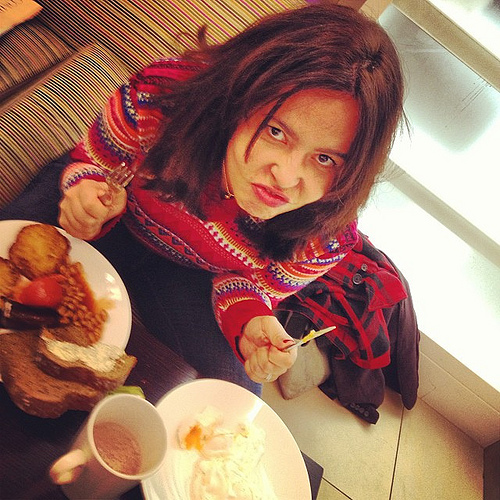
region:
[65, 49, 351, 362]
a red winter holiday sweater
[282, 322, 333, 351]
a silver knife utensil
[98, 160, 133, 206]
a silver fork utensil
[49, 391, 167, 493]
a white coffee mug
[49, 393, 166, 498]
a mug of hot cocoa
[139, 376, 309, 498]
a white dinner plate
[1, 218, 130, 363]
a white dinner plate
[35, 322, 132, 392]
a slice of toast with butter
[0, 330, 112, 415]
a slice of toast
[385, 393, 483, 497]
a white floor tile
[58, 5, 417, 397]
Woman sitting on a couch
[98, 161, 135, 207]
Fork in the woman's right hand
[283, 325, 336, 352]
Knife in the woman's left hand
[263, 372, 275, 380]
Ring on the woman's finger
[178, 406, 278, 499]
Fried eggs on a white plate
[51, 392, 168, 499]
Mug on the table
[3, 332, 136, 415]
Two pieces of bread on the plate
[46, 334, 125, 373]
Butte on the bread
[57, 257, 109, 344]
Beans on the plate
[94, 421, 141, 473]
Drink in the mug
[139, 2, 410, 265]
the girl has brown straight hair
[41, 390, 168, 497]
a coffee cup is on the table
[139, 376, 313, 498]
a pink plate is on the table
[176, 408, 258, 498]
poached eggs are on the plate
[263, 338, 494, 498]
the floor is tiled with brown grout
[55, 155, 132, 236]
a fork is in the girl's hand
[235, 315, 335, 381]
a knife is in the girl's hand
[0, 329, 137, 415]
brown bread is on the table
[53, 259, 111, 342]
beans are on the dish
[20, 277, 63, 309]
a tomato is in the center of the dish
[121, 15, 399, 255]
The woman looks very unhappy.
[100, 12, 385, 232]
This is a woman.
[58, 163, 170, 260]
The woman is holding a fork.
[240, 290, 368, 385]
The woman is holding a knife.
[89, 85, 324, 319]
The womans has on a red sweater.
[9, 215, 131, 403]
This looks like breakfast food.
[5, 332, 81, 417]
This is toasted bread.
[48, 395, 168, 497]
This is a coffee mug.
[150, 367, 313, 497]
This is a plate.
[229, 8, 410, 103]
The woman has brown hair.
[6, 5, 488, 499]
woman is preparing to eat a meal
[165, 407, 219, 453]
A cooked egg with exposed yolk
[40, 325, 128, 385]
A slice of buttered bread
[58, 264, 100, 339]
beans in a red sauce on a white and grey polka dot plate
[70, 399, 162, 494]
a beige mug with a beverage in it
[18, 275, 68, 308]
a cooked red tomato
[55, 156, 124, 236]
right hand clutching fork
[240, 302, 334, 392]
left hand clutching a butter knife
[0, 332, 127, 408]
One slice has butter the other does not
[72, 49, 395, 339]
woman wearing a red patterned sweater